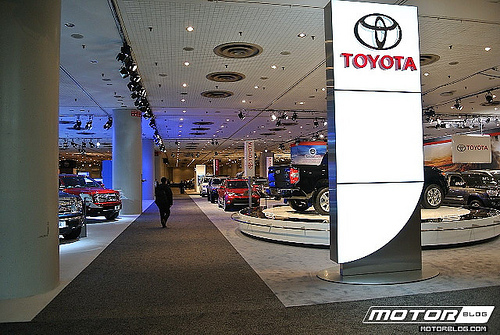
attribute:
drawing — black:
[351, 10, 401, 50]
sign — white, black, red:
[321, 0, 426, 283]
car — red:
[219, 175, 260, 215]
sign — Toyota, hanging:
[336, 7, 435, 79]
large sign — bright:
[323, 0, 423, 275]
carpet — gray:
[115, 234, 252, 311]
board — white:
[321, 0, 428, 281]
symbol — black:
[350, 10, 405, 52]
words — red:
[334, 46, 455, 84]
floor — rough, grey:
[147, 195, 199, 331]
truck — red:
[71, 181, 121, 211]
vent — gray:
[211, 37, 266, 60]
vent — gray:
[206, 69, 246, 82]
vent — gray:
[195, 85, 235, 103]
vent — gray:
[190, 118, 212, 127]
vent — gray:
[189, 129, 209, 139]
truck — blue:
[57, 184, 83, 243]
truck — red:
[58, 170, 125, 221]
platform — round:
[235, 203, 498, 245]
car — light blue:
[54, 186, 84, 243]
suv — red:
[215, 174, 258, 214]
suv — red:
[59, 172, 120, 219]